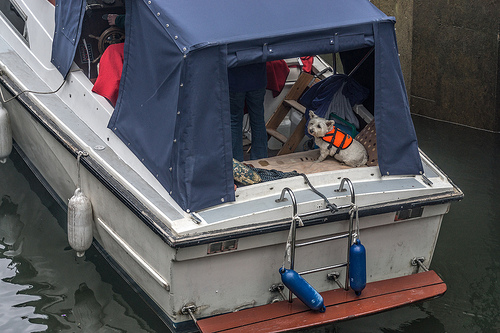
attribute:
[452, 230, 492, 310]
grey water — gray, dirty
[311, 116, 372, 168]
dog — white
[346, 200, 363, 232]
rope — blue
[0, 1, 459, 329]
ship — white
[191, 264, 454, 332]
plank — wooden, standing platform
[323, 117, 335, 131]
ear — left ear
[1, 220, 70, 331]
water — calm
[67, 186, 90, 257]
container — small, white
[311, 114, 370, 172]
dog — small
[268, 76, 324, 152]
step ladder — small, wooden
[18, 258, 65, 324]
water — dirty, gray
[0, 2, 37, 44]
window — glass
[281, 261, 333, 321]
tank — oxygen, blue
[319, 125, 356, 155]
jacket — life jacket 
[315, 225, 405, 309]
floater — blue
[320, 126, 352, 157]
life vest — orange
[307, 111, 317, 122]
ear — right ear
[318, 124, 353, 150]
life vest — orange